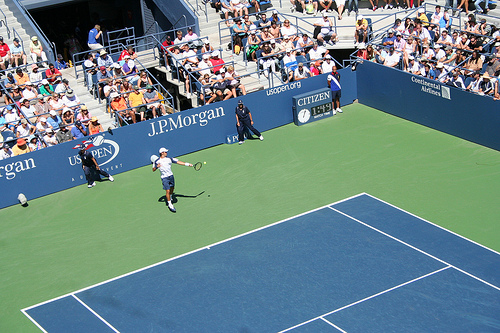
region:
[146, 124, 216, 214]
a man holding a tennis racket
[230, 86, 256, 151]
a man wearing black clothes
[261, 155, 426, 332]
a blue and green tennis court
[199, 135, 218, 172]
a yellow tennis ball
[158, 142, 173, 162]
a man wearing a white hat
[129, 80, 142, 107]
a man wearing a yellow shirt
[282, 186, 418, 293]
white lines on a tennis court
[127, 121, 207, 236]
a man playing tennis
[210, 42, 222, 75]
a person wearing a red shirt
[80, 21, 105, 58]
a person wearing a blue shirt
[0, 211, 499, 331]
Green and blue tennis court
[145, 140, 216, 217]
Tennis player hitting the ball his racquet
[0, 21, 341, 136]
Spectators in the stands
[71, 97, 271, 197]
Tennis player with the ball boys behind him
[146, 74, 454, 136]
Ad space at a tennis match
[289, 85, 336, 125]
Official game clock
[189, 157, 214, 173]
Tennis racquet and ball about to make contact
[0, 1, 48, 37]
White steps with blue handrails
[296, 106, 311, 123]
Round white analog clock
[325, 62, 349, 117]
Man leaning against partition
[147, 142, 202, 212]
man swinging tennis raquet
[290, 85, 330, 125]
blue clock on a wall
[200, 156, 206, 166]
tennis ball flying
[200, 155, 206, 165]
flying tennis ball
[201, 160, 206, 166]
tennis ball flying in the air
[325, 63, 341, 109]
man standing on a wall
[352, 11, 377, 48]
person sitting in a chair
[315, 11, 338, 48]
person sitting in a chair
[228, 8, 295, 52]
people sitting in chairs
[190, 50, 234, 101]
people sitting in chairs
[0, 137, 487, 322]
A tennis match being played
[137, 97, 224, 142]
J.P. Morgan advertisement on the wall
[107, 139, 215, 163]
The wall is blue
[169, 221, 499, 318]
The tennis court is blue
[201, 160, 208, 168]
A small green tennis ball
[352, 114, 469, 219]
The outer edge of the court is green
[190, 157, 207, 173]
A black tennis racket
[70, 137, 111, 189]
A running tennis referee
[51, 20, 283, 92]
A crowd watching the game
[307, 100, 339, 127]
The clock says 1:49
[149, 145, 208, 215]
tennis player about to hit ball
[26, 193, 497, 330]
Blue tennis court with green surrounding field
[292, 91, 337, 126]
Citizen branded time clock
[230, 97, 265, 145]
Tennis referee.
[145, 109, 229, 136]
J.P. Morgan Ad on wall.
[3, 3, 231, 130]
Spectators sitting in audience bleachers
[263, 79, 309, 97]
usopen.org logo on wall of tennis match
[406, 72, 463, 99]
Continental Airlines Ad on wall of tennis match court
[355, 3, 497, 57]
People sitting in cement and metal railed bleachers.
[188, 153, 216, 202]
Tennis raquet about to hit ball with shadow